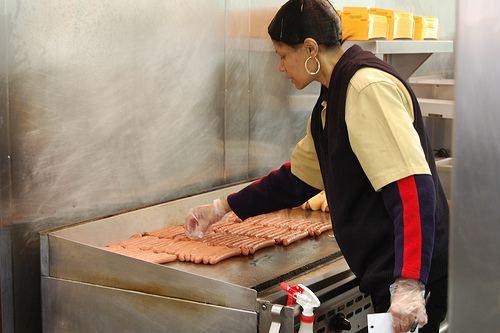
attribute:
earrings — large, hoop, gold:
[307, 52, 321, 77]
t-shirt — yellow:
[289, 69, 432, 191]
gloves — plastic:
[187, 194, 215, 240]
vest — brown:
[307, 43, 447, 292]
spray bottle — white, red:
[278, 279, 321, 333]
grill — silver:
[43, 171, 379, 332]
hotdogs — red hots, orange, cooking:
[111, 206, 331, 263]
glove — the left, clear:
[391, 279, 431, 332]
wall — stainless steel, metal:
[5, 7, 275, 218]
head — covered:
[270, 0, 349, 90]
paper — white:
[367, 312, 396, 327]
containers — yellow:
[340, 5, 442, 41]